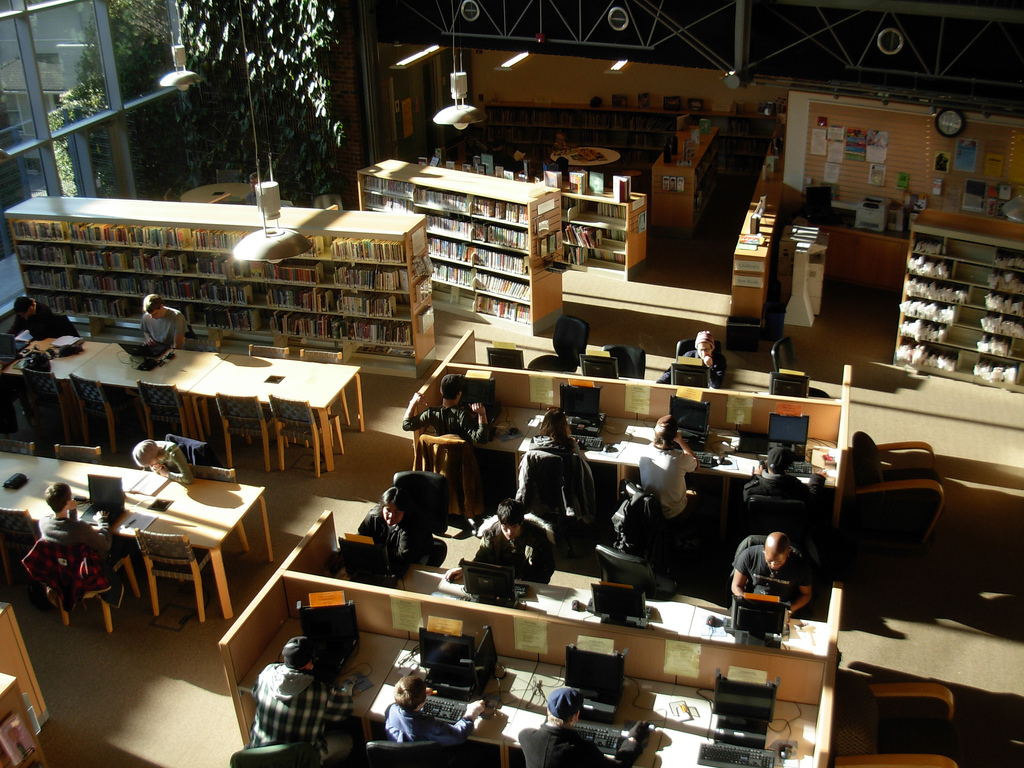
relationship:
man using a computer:
[207, 591, 337, 768] [296, 598, 355, 653]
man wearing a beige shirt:
[633, 399, 700, 510] [644, 442, 675, 495]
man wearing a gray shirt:
[112, 282, 221, 376] [156, 315, 172, 337]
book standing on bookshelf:
[599, 166, 636, 203] [614, 218, 641, 251]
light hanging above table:
[156, 109, 213, 112] [153, 203, 203, 229]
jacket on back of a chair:
[33, 552, 100, 596] [19, 542, 117, 741]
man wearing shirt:
[248, 634, 359, 756] [248, 660, 344, 753]